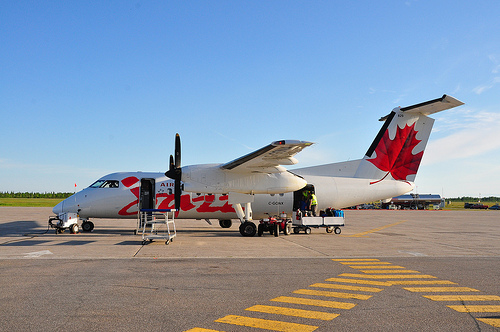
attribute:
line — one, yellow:
[455, 300, 498, 316]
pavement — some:
[174, 254, 261, 288]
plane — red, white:
[42, 108, 448, 255]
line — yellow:
[257, 277, 315, 323]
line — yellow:
[375, 213, 396, 244]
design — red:
[366, 120, 423, 187]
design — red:
[117, 174, 232, 219]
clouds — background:
[391, 115, 491, 205]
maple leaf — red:
[364, 117, 430, 187]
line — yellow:
[178, 242, 485, 330]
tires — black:
[74, 217, 100, 234]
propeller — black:
[165, 127, 185, 213]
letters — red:
[118, 176, 255, 221]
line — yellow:
[180, 270, 393, 330]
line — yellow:
[270, 289, 358, 313]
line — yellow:
[327, 271, 381, 283]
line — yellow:
[387, 273, 461, 289]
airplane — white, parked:
[53, 91, 465, 234]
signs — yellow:
[196, 253, 485, 321]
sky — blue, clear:
[6, 8, 483, 189]